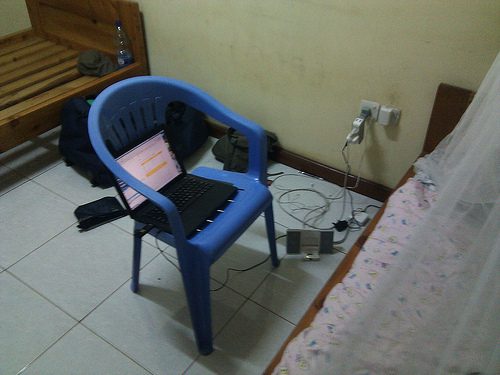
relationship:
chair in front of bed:
[88, 76, 283, 353] [267, 84, 497, 372]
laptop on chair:
[107, 123, 234, 236] [88, 76, 283, 353]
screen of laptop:
[114, 133, 180, 208] [107, 123, 234, 236]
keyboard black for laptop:
[144, 176, 213, 221] [107, 123, 234, 236]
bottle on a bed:
[113, 21, 135, 66] [0, 2, 151, 158]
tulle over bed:
[272, 52, 499, 372] [267, 84, 497, 372]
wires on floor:
[154, 172, 380, 290] [1, 127, 388, 373]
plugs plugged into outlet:
[339, 106, 369, 192] [361, 101, 380, 119]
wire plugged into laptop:
[155, 231, 293, 292] [107, 123, 234, 236]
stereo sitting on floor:
[287, 231, 332, 260] [1, 127, 388, 373]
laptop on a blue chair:
[107, 123, 234, 236] [88, 76, 283, 353]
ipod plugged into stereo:
[353, 209, 370, 227] [287, 231, 332, 260]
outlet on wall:
[361, 101, 380, 119] [138, 4, 500, 186]